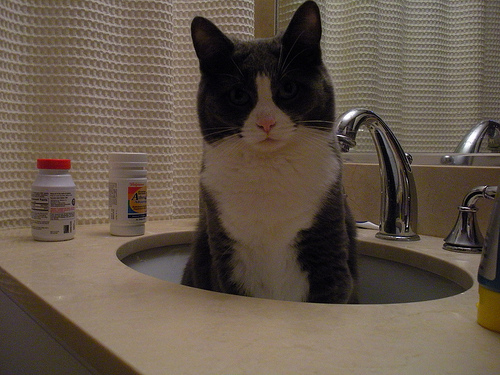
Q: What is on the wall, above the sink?
A: A mirror.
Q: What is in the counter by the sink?
A: Two bottles.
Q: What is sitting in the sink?
A: A cat.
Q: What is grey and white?
A: The cat.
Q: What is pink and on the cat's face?
A: The nose.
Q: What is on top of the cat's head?
A: The ears.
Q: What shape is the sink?
A: Oval.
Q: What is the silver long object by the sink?
A: The faucet.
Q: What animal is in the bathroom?
A: A cat.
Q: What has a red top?
A: A medicine bottle.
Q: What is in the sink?
A: A cat.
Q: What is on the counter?
A: Bottles of medicine.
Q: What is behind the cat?
A: The faucet.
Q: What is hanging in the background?
A: A shower curtain.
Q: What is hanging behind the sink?
A: A mirror.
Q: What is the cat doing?
A: Sitting in the sink.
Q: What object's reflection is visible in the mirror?
A: The faucet's.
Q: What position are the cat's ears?
A: Perked upward.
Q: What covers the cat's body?
A: Fur.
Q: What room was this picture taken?
A: The bathroom.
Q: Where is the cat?
A: Sitting in the sink.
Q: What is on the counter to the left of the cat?
A: Two bottles of pills.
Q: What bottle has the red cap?
A: The one on the left.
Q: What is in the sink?
A: A cat.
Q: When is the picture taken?
A: Night time.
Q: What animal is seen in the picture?
A: Cat.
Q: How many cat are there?
A: One.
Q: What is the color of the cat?
A: Black and white.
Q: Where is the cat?
A: Sitting in the basin.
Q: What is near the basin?
A: 2 medicine bottles.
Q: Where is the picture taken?
A: In the bathroom.